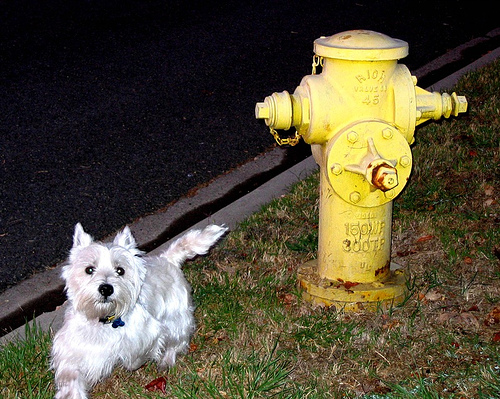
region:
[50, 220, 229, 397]
small, white dog on the grass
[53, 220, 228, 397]
small, cute dog laying on the grass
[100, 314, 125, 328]
blue collar around dog's neck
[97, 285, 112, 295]
small black nose of dog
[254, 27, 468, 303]
yellow fire hydrant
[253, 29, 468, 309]
fire hydrant next to dog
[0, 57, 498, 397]
patches of grass with dried leaves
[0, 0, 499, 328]
road made of asphalt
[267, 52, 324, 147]
chain on fire hydrant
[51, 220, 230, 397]
white dog with blue collar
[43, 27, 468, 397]
a white dog and a yellow fire hydrant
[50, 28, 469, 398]
a dog and a fire hydrant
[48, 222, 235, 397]
a white dog looking at the camera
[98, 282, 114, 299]
a black nose of the dog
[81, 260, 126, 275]
black eyes of the dog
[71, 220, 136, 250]
two ears of the dog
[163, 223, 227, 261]
a tail of the dog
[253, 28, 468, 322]
a fire hydrant on the sidewalk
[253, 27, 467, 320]
a yellow fire hydrant on the sidewalk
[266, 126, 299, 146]
a chain on the fire hydrant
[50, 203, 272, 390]
This is a small dog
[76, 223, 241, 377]
The dog is white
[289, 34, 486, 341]
This is a fire hydrant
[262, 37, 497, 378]
The hydrant is yellow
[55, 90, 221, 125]
This is a street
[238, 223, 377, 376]
This is a patch of grass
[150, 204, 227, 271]
This is a tail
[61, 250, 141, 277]
These are the dog's eyes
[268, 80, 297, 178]
This is a chain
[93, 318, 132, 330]
This is a collar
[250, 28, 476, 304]
A water hydrant.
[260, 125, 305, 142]
A chain in the photo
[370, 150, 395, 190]
A nut on the hydrant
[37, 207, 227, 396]
A white dog in the photo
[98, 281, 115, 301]
Black muzzle of the dog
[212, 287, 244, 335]
Green grass in the photo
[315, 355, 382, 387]
Dry grass in the photo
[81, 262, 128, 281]
Black eyes of the dog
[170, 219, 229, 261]
White tail of the dog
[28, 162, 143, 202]
A road with tarmac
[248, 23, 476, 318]
yellow fire hydrant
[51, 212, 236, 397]
white dog near fire hydrant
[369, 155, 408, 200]
rust covered bolt on hydrant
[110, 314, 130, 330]
blue name tag on dog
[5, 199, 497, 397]
small white dog laying on the grass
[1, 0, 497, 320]
dark grey pavement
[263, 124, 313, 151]
chain covered with yellow paint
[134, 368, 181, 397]
small red leaf in grass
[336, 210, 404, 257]
raised lettering on fire hydrant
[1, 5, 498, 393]
fire hydrant near small white dog